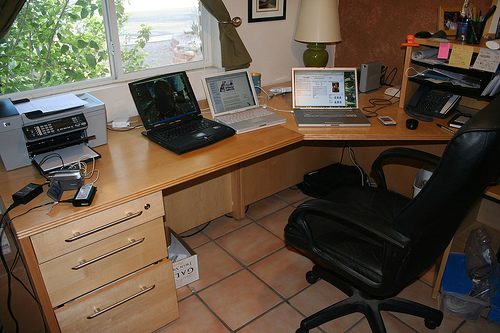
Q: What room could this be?
A: It is an office.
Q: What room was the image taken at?
A: It was taken at the office.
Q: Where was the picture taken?
A: It was taken at the office.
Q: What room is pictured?
A: It is an office.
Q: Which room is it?
A: It is an office.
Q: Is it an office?
A: Yes, it is an office.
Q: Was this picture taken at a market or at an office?
A: It was taken at an office.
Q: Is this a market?
A: No, it is an office.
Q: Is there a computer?
A: Yes, there is a computer.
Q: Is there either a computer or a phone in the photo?
A: Yes, there is a computer.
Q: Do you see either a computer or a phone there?
A: Yes, there is a computer.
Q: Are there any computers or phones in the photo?
A: Yes, there is a computer.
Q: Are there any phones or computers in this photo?
A: Yes, there is a computer.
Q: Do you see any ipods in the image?
A: No, there are no ipods.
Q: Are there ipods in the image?
A: No, there are no ipods.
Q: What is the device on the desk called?
A: The device is a computer.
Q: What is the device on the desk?
A: The device is a computer.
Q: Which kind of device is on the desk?
A: The device is a computer.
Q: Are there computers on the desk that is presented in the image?
A: Yes, there is a computer on the desk.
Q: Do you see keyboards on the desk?
A: No, there is a computer on the desk.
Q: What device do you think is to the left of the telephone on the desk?
A: The device is a computer.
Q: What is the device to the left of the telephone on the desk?
A: The device is a computer.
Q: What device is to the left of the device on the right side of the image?
A: The device is a computer.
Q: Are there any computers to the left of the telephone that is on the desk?
A: Yes, there is a computer to the left of the phone.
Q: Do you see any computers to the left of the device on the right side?
A: Yes, there is a computer to the left of the phone.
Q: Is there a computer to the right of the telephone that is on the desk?
A: No, the computer is to the left of the phone.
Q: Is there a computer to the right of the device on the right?
A: No, the computer is to the left of the phone.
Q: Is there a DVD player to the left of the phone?
A: No, there is a computer to the left of the phone.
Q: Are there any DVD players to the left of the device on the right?
A: No, there is a computer to the left of the phone.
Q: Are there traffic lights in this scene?
A: No, there are no traffic lights.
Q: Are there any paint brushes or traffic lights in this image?
A: No, there are no traffic lights or paint brushes.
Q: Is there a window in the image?
A: Yes, there is a window.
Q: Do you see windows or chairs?
A: Yes, there is a window.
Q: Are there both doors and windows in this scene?
A: No, there is a window but no doors.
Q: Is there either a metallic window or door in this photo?
A: Yes, there is a metal window.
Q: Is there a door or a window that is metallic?
A: Yes, the window is metallic.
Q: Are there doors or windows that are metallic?
A: Yes, the window is metallic.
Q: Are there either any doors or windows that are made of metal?
A: Yes, the window is made of metal.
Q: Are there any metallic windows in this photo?
A: Yes, there is a metal window.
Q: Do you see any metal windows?
A: Yes, there is a metal window.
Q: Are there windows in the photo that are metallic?
A: Yes, there is a window that is metallic.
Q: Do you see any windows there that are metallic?
A: Yes, there is a window that is metallic.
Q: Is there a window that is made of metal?
A: Yes, there is a window that is made of metal.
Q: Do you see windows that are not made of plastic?
A: Yes, there is a window that is made of metal.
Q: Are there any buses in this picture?
A: No, there are no buses.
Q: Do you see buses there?
A: No, there are no buses.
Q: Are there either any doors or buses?
A: No, there are no buses or doors.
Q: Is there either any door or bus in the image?
A: No, there are no buses or doors.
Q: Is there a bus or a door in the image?
A: No, there are no buses or doors.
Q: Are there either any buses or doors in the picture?
A: No, there are no buses or doors.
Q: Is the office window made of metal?
A: Yes, the window is made of metal.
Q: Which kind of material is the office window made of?
A: The window is made of metal.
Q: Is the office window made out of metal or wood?
A: The window is made of metal.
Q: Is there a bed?
A: No, there are no beds.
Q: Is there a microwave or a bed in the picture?
A: No, there are no beds or microwaves.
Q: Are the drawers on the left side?
A: Yes, the drawers are on the left of the image.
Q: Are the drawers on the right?
A: No, the drawers are on the left of the image.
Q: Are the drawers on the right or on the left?
A: The drawers are on the left of the image.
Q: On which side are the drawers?
A: The drawers are on the left of the image.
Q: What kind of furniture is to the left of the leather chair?
A: The pieces of furniture are drawers.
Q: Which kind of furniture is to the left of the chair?
A: The pieces of furniture are drawers.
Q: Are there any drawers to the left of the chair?
A: Yes, there are drawers to the left of the chair.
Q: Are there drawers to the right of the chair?
A: No, the drawers are to the left of the chair.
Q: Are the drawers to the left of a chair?
A: Yes, the drawers are to the left of a chair.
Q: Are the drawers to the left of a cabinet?
A: No, the drawers are to the left of a chair.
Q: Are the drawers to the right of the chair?
A: No, the drawers are to the left of the chair.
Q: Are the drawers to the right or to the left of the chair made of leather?
A: The drawers are to the left of the chair.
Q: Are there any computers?
A: Yes, there is a computer.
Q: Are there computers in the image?
A: Yes, there is a computer.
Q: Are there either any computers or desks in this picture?
A: Yes, there is a computer.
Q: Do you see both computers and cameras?
A: No, there is a computer but no cameras.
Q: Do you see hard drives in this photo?
A: No, there are no hard drives.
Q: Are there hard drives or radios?
A: No, there are no hard drives or radios.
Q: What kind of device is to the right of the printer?
A: The device is a computer.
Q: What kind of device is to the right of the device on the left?
A: The device is a computer.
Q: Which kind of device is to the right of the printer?
A: The device is a computer.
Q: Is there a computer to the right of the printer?
A: Yes, there is a computer to the right of the printer.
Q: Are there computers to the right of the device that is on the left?
A: Yes, there is a computer to the right of the printer.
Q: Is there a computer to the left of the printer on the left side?
A: No, the computer is to the right of the printer.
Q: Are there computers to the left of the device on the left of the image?
A: No, the computer is to the right of the printer.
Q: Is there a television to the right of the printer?
A: No, there is a computer to the right of the printer.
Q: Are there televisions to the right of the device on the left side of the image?
A: No, there is a computer to the right of the printer.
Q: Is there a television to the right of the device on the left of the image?
A: No, there is a computer to the right of the printer.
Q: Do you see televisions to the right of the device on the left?
A: No, there is a computer to the right of the printer.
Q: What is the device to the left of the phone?
A: The device is a computer.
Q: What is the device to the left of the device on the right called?
A: The device is a computer.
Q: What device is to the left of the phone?
A: The device is a computer.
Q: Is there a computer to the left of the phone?
A: Yes, there is a computer to the left of the phone.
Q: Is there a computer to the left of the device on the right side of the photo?
A: Yes, there is a computer to the left of the phone.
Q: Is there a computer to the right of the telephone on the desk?
A: No, the computer is to the left of the telephone.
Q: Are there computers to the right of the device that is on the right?
A: No, the computer is to the left of the telephone.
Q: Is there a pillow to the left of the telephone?
A: No, there is a computer to the left of the telephone.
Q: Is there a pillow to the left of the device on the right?
A: No, there is a computer to the left of the telephone.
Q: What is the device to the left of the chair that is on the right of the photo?
A: The device is a computer.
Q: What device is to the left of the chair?
A: The device is a computer.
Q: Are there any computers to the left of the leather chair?
A: Yes, there is a computer to the left of the chair.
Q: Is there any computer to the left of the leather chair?
A: Yes, there is a computer to the left of the chair.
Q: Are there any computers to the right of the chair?
A: No, the computer is to the left of the chair.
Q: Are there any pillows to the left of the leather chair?
A: No, there is a computer to the left of the chair.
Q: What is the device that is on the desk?
A: The device is a computer.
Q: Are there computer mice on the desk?
A: No, there is a computer on the desk.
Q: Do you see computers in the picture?
A: Yes, there is a computer.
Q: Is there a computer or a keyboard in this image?
A: Yes, there is a computer.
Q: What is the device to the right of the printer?
A: The device is a computer.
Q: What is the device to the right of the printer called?
A: The device is a computer.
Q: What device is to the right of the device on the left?
A: The device is a computer.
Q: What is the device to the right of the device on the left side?
A: The device is a computer.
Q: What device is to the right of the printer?
A: The device is a computer.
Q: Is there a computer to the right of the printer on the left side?
A: Yes, there is a computer to the right of the printer.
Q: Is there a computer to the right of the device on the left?
A: Yes, there is a computer to the right of the printer.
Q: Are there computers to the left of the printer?
A: No, the computer is to the right of the printer.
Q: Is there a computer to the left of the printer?
A: No, the computer is to the right of the printer.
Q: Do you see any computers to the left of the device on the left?
A: No, the computer is to the right of the printer.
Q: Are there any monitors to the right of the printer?
A: No, there is a computer to the right of the printer.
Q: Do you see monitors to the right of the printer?
A: No, there is a computer to the right of the printer.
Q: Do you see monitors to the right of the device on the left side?
A: No, there is a computer to the right of the printer.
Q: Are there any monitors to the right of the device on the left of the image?
A: No, there is a computer to the right of the printer.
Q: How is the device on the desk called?
A: The device is a computer.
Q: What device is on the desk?
A: The device is a computer.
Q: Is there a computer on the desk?
A: Yes, there is a computer on the desk.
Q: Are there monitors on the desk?
A: No, there is a computer on the desk.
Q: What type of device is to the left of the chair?
A: The device is a computer.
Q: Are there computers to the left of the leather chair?
A: Yes, there is a computer to the left of the chair.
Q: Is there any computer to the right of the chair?
A: No, the computer is to the left of the chair.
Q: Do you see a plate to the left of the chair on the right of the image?
A: No, there is a computer to the left of the chair.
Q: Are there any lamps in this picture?
A: Yes, there is a lamp.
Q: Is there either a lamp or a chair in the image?
A: Yes, there is a lamp.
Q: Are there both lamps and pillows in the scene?
A: No, there is a lamp but no pillows.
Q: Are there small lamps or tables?
A: Yes, there is a small lamp.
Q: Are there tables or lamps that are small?
A: Yes, the lamp is small.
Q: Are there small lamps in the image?
A: Yes, there is a small lamp.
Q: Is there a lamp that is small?
A: Yes, there is a lamp that is small.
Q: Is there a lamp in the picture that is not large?
A: Yes, there is a small lamp.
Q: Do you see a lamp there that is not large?
A: Yes, there is a small lamp.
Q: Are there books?
A: No, there are no books.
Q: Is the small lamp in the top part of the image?
A: Yes, the lamp is in the top of the image.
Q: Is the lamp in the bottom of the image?
A: No, the lamp is in the top of the image.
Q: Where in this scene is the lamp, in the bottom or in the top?
A: The lamp is in the top of the image.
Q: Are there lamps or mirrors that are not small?
A: No, there is a lamp but it is small.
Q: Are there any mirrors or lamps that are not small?
A: No, there is a lamp but it is small.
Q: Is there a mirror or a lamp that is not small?
A: No, there is a lamp but it is small.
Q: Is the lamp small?
A: Yes, the lamp is small.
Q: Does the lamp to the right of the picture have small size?
A: Yes, the lamp is small.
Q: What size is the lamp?
A: The lamp is small.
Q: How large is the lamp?
A: The lamp is small.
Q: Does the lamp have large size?
A: No, the lamp is small.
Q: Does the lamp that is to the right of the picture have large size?
A: No, the lamp is small.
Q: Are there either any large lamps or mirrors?
A: No, there is a lamp but it is small.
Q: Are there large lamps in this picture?
A: No, there is a lamp but it is small.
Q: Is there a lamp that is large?
A: No, there is a lamp but it is small.